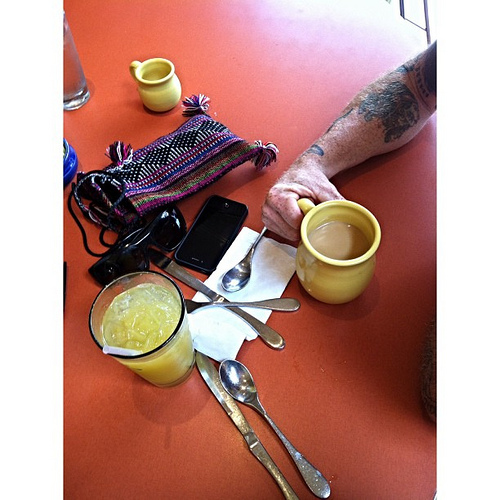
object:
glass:
[152, 294, 195, 388]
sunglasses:
[88, 205, 187, 285]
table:
[63, 0, 435, 498]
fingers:
[261, 193, 348, 241]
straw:
[102, 345, 143, 356]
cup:
[88, 270, 196, 390]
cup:
[127, 57, 181, 114]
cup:
[62, 9, 89, 111]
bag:
[74, 93, 280, 225]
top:
[235, 69, 323, 103]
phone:
[174, 193, 248, 274]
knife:
[193, 350, 300, 500]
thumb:
[310, 182, 345, 200]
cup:
[295, 199, 381, 306]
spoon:
[221, 226, 267, 293]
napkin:
[185, 227, 299, 362]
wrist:
[290, 138, 343, 176]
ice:
[101, 282, 181, 353]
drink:
[101, 282, 193, 384]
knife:
[148, 248, 287, 352]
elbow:
[395, 47, 437, 128]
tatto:
[301, 45, 435, 160]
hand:
[260, 163, 344, 241]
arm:
[282, 41, 438, 179]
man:
[261, 39, 437, 241]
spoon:
[218, 359, 331, 499]